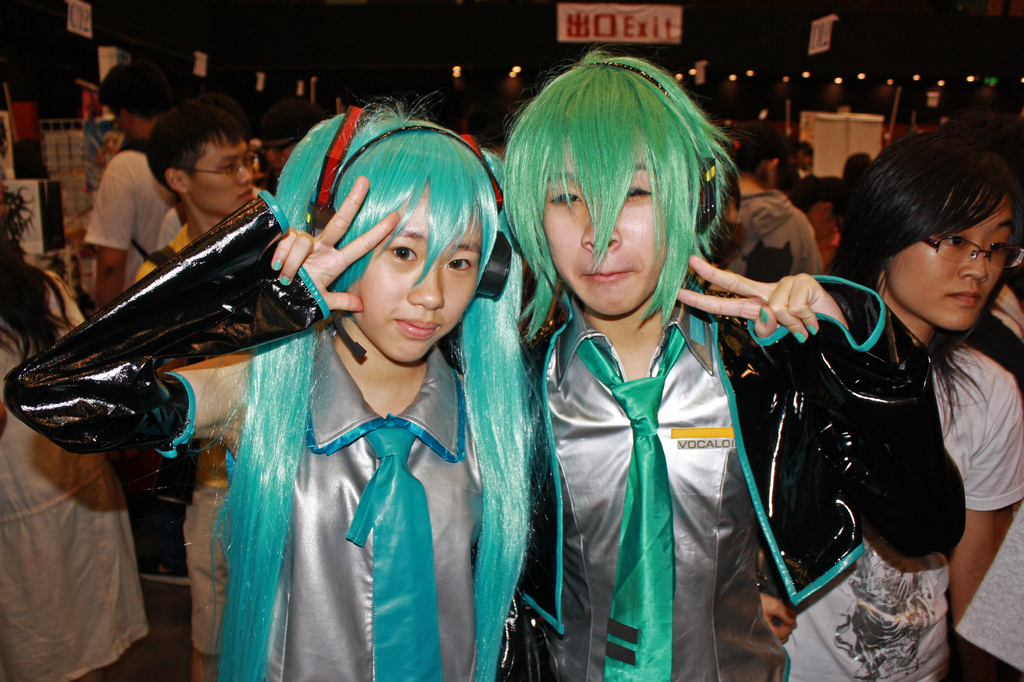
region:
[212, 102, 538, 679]
Woman with blue hair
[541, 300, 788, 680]
Man in a silver shirt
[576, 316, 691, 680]
Man is wearing a green tie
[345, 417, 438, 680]
Woman is wearing a blue tie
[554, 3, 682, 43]
White sign with red letters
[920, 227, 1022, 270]
Woman is wearing glasses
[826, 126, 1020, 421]
Woman has dark hair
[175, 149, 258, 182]
Man is wearing glasses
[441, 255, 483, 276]
eye of the person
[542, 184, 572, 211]
eye of the person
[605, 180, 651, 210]
eye of the person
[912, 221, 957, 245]
eye of the person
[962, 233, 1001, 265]
eye of the person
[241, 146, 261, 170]
eye of the person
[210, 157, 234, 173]
eye of the person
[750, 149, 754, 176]
eye of the person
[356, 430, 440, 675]
The blue tie the person on the left is wearing.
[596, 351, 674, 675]
The green tie the person on the right is wearing.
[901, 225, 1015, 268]
The eye glasses the lady is wearing on the right.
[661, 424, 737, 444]
The yellow stripe on the person's gray shirt.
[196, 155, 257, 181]
The eyeglasses the man behind the girl is wearing.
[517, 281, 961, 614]
The black and teal jacket the person is wearing.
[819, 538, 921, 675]
The black design on the lady's shirt.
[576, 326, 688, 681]
A green tie.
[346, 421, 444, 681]
A blue shiny tie.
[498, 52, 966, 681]
A green haired guy in silver shirt.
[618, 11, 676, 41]
The red word Exit.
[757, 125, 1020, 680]
Black haired girl with thin framed glasses on and a white shirt.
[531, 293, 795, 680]
Silver shirt on a guy.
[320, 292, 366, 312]
Right hand thumb on the blue haired person.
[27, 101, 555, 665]
the woman to the left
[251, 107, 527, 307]
The wig on the left woman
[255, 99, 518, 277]
A wig on the left woman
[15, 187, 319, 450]
The glove on the lft arm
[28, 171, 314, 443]
A sleeve on the left arm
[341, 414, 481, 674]
The blue tie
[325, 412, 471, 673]
A blue tie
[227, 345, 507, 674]
The shirt on the left woman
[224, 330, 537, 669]
A shirt on the left woman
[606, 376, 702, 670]
The tie is green.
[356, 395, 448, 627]
the tie is blue.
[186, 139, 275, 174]
The person is wearing glasses.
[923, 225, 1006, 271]
The girl is wearing glasses.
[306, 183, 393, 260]
The person is holding up two fingers.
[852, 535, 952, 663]
The shirt has a gray design.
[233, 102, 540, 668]
blue wig on a girl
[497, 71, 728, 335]
green wig on a boy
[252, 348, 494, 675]
silver shirt on a girl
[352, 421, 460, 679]
blue tie on a girl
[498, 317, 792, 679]
silver shirt on a boy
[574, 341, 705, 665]
green tie on a boy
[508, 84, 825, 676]
A person is standing up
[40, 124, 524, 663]
A person is standing up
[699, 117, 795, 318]
A person is standing up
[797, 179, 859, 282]
A person is standing up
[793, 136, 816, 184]
A person is standing up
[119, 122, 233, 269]
A person is standing up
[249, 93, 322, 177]
A person is standing up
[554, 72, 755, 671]
A person with a green tIE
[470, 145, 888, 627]
Garlic black jacket on